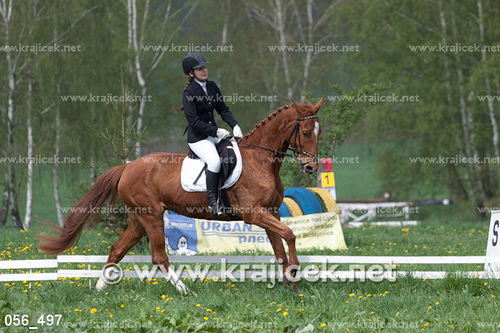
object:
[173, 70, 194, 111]
braids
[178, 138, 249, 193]
saddle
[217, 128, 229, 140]
white glove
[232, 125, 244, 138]
white glove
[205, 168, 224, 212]
riding boot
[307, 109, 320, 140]
spot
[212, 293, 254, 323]
grass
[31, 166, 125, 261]
tail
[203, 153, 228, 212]
boot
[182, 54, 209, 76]
helmet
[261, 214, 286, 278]
leg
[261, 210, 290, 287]
leg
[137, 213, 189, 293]
leg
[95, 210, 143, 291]
leg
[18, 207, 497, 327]
field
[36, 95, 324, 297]
brown horse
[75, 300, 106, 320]
flowers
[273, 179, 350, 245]
painted tires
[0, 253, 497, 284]
fence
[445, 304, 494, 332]
grass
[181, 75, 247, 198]
outfit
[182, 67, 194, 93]
hair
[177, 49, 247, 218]
jockey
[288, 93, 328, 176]
head